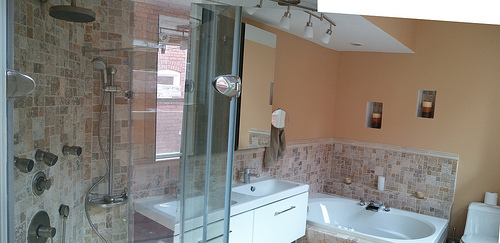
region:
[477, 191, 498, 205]
The toilet paper is on the toilet.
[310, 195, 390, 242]
The bathtub is white.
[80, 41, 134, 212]
A hand held shower.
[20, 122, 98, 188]
The showers has body sprays.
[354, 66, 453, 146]
Two cut outs on the wall.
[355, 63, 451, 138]
Two candles in the cut outs.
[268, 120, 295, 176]
a brown towel by the bathtub.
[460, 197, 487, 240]
The toilet is white.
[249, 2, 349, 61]
The lights are off.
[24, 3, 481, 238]
The room is a bathroom.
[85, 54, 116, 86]
the shower head on the wall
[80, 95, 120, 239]
the chord for the showerhead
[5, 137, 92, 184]
water jets on the wall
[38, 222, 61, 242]
the knozzel for the water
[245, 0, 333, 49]
a row of loights on the ceiling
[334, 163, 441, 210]
candles on the ledge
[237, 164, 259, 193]
the sink faucet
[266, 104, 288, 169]
the toel on the wall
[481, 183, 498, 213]
a roll of toilet paper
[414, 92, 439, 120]
a candle in the wall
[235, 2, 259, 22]
vanity light above sink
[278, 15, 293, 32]
vanity light above sink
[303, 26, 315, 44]
vanity light above sink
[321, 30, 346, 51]
vanity light above sink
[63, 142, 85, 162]
knob on shower wall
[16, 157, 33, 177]
knob on shower wall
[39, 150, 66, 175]
knob on shower wall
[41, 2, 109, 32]
shower head in shower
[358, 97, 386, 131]
candle holder in wall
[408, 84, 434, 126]
candle holder in wall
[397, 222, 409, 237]
the sink is white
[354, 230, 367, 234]
the sink is white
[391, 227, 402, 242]
the sink is white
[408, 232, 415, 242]
the sink is white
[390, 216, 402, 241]
the sink is white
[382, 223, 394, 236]
the sink is white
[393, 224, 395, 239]
the sink is white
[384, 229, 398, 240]
the sink is white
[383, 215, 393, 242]
the sink is white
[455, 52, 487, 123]
The wall is light brown.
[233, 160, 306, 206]
A sink in the bathroom.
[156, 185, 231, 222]
Another sink in the bathroom.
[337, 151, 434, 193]
Tiles on the wall.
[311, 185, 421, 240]
A large white bathtub.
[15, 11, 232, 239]
A clear partition for the shower.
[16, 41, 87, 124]
Tiles on the wall of the shower.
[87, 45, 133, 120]
The shower head is made out of metal.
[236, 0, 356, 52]
Lights on the ceiling.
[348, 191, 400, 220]
The faucet on the bathtub.